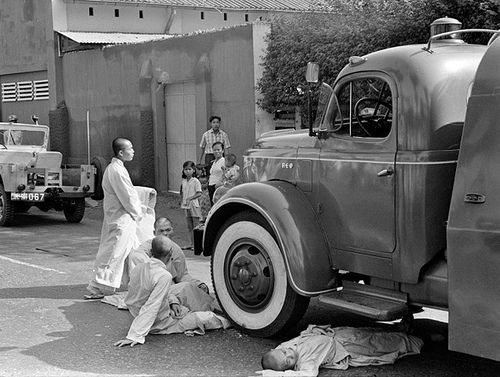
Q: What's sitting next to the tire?
A: Two men.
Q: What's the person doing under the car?
A: Lying down.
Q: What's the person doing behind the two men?
A: Walking.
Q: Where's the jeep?
A: Beside the building.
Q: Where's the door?
A: Beside the man.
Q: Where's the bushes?
A: Behind the truck.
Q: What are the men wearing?
A: Robes.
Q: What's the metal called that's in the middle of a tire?
A: Rim.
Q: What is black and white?
A: The picture.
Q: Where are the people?
A: By the truck.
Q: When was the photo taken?
A: During the daytime.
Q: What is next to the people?
A: The truck.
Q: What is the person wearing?
A: A white robe.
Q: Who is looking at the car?
A: Monks.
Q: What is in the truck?
A: A steering wheel.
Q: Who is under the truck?
A: A person.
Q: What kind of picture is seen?
A: Black and white.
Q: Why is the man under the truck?
A: Protest.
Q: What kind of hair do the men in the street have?
A: Shaved.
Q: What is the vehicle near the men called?
A: Truck.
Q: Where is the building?
A: Background.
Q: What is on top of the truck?
A: Light.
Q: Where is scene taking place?
A: Outside a factory.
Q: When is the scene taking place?
A: Morning.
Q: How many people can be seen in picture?
A: 8.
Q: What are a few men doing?
A: Working on a truck.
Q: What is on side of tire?
A: White wall.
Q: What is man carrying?
A: A blanket.